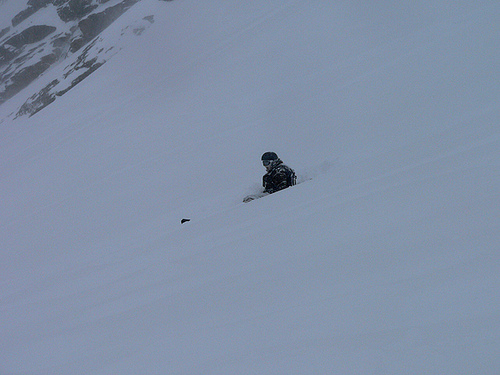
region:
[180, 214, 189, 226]
the tip of a foot in the snow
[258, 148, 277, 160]
the black hat of a person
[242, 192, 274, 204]
the white pants of a person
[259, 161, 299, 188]
the black jacket of a person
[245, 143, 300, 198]
a snow covered person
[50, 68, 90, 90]
a patch of snow on a grey rock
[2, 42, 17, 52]
a patch of snow on a grey rock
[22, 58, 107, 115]
a snow covered rock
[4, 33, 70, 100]
a snow covered rock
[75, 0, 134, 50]
a snow covered rock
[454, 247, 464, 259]
part of a white surface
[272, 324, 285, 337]
section of the snow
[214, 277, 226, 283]
part of a white slope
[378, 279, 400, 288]
part of a mountain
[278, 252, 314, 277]
top of a mountain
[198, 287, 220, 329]
white part on a mountain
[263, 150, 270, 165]
head of a man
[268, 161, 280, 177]
part of a jacket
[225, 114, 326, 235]
a person in the snow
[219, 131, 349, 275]
a person sitting in the snow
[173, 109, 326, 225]
a person surrounded by snow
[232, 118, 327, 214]
a person wearing black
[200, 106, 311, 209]
a person down in the snow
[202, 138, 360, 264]
a person covered in snow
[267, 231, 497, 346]
white snow on the ground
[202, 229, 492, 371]
snow on the ground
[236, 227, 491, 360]
the ground cover in snow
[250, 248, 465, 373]
ground covered in white snow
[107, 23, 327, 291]
the man is covered with snow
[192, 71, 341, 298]
the man is covered with snow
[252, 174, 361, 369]
the man is covered with snow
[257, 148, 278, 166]
the head of someone halfway in the snow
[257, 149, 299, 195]
a person in the snow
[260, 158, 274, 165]
the goggles of a person in the snow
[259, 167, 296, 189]
the black jacket of a person in the snow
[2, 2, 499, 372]
a snow covered slope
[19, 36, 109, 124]
a snow covered grey rock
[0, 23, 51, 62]
a snow covered grey rock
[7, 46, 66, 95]
a snow covered grey rock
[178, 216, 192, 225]
the black tip of a foot